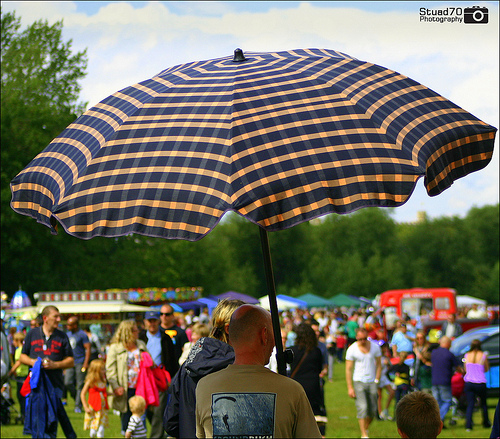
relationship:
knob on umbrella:
[233, 47, 243, 63] [8, 46, 498, 368]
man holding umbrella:
[194, 304, 323, 438] [14, 41, 494, 243]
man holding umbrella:
[211, 320, 286, 414] [162, 87, 348, 163]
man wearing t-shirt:
[211, 320, 286, 414] [211, 379, 274, 405]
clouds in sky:
[2, 6, 497, 221] [2, 2, 494, 61]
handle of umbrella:
[256, 229, 291, 373] [31, 15, 491, 267]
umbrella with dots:
[14, 41, 494, 243] [287, 132, 352, 177]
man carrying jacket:
[11, 302, 84, 437] [20, 352, 68, 437]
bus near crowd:
[356, 274, 467, 336] [15, 290, 490, 437]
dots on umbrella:
[168, 148, 283, 172] [14, 41, 494, 243]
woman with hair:
[107, 321, 162, 406] [112, 311, 129, 336]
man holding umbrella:
[194, 304, 323, 438] [31, 15, 491, 267]